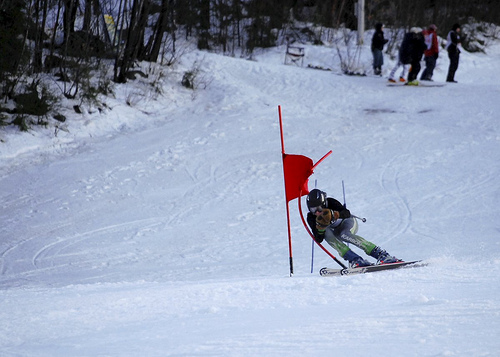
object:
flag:
[277, 104, 348, 277]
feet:
[350, 260, 365, 270]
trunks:
[0, 213, 163, 272]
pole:
[274, 103, 295, 276]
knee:
[320, 227, 338, 242]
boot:
[350, 260, 372, 269]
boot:
[375, 252, 402, 264]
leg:
[321, 227, 361, 263]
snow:
[0, 24, 499, 355]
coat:
[305, 197, 353, 245]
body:
[304, 196, 406, 271]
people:
[441, 21, 469, 84]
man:
[306, 188, 404, 270]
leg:
[337, 220, 379, 258]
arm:
[329, 198, 354, 220]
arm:
[306, 212, 327, 242]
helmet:
[304, 187, 330, 214]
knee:
[337, 228, 355, 240]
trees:
[112, 0, 152, 85]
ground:
[0, 40, 500, 356]